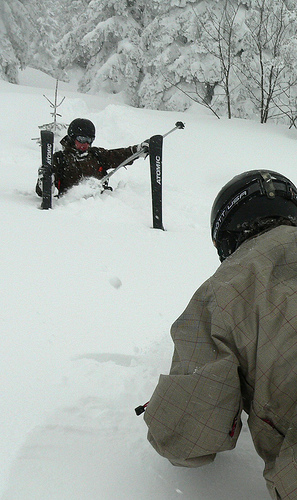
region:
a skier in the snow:
[21, 105, 185, 253]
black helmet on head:
[192, 155, 294, 242]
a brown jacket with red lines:
[150, 234, 295, 494]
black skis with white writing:
[29, 124, 182, 245]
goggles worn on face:
[64, 124, 94, 151]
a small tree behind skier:
[22, 67, 83, 178]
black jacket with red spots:
[36, 144, 134, 202]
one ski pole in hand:
[81, 134, 235, 208]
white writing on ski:
[155, 152, 162, 191]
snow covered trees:
[8, 16, 293, 93]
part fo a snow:
[92, 438, 117, 471]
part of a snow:
[88, 424, 116, 462]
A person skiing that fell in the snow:
[51, 120, 171, 238]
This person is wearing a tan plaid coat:
[145, 290, 287, 467]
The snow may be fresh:
[37, 309, 92, 444]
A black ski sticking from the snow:
[143, 118, 168, 239]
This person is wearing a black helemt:
[203, 160, 289, 235]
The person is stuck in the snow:
[34, 89, 188, 243]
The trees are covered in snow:
[145, 14, 256, 124]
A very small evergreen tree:
[44, 78, 72, 146]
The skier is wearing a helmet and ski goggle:
[65, 117, 97, 156]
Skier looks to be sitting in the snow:
[30, 100, 140, 219]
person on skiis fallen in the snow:
[23, 101, 193, 238]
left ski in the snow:
[142, 129, 175, 239]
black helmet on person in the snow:
[198, 164, 294, 260]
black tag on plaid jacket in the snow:
[128, 394, 155, 417]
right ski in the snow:
[33, 126, 59, 213]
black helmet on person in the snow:
[61, 112, 99, 141]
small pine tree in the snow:
[35, 70, 71, 135]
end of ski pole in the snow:
[170, 117, 192, 134]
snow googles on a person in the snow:
[68, 130, 99, 145]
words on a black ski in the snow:
[153, 154, 164, 187]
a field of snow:
[0, 79, 296, 498]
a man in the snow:
[134, 169, 296, 499]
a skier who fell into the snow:
[34, 117, 149, 198]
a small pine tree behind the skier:
[30, 79, 69, 151]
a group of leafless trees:
[158, 0, 295, 128]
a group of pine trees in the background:
[0, 0, 296, 125]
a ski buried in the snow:
[148, 134, 163, 228]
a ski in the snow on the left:
[39, 129, 53, 209]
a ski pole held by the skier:
[98, 121, 184, 184]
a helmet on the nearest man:
[210, 169, 296, 247]